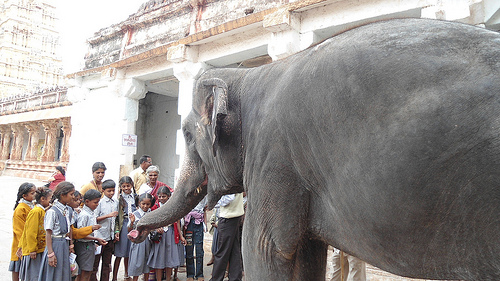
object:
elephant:
[125, 17, 499, 280]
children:
[6, 182, 40, 281]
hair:
[44, 181, 76, 212]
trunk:
[127, 121, 210, 244]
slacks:
[72, 241, 97, 272]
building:
[0, 0, 500, 185]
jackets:
[16, 204, 47, 256]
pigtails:
[13, 182, 34, 210]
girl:
[109, 175, 140, 281]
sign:
[122, 134, 139, 147]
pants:
[90, 241, 114, 281]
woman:
[79, 161, 108, 198]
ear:
[194, 77, 230, 157]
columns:
[56, 117, 70, 165]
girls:
[36, 181, 77, 281]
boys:
[73, 188, 110, 281]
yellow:
[24, 210, 40, 248]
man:
[125, 154, 156, 196]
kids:
[125, 192, 165, 281]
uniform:
[37, 200, 75, 281]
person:
[40, 165, 66, 192]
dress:
[146, 224, 187, 270]